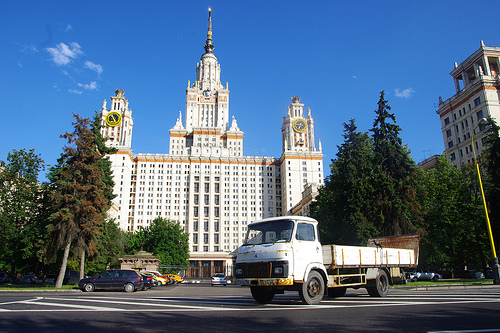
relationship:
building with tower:
[52, 22, 384, 295] [280, 95, 323, 157]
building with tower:
[52, 22, 384, 295] [169, 6, 246, 155]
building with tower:
[52, 22, 384, 295] [97, 87, 133, 154]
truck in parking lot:
[229, 215, 421, 305] [0, 280, 495, 329]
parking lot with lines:
[80, 246, 250, 330] [5, 287, 495, 308]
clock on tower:
[292, 116, 307, 133] [281, 95, 323, 154]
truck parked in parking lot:
[231, 215, 420, 305] [85, 283, 248, 291]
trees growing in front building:
[368, 113, 434, 210] [93, 2, 325, 281]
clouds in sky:
[39, 30, 97, 70] [121, 26, 180, 71]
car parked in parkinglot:
[148, 267, 184, 287] [16, 267, 495, 324]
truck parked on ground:
[229, 215, 421, 305] [0, 282, 500, 333]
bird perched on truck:
[369, 229, 384, 254] [229, 215, 421, 305]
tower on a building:
[70, 75, 158, 180] [8, 11, 394, 310]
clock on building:
[292, 118, 307, 132] [93, 2, 325, 281]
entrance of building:
[185, 255, 228, 277] [93, 2, 325, 281]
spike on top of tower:
[200, 4, 220, 55] [180, 0, 237, 131]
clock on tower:
[292, 118, 307, 132] [267, 86, 329, 193]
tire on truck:
[305, 271, 330, 303] [236, 210, 431, 302]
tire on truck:
[363, 264, 393, 299] [229, 215, 421, 305]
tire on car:
[123, 279, 138, 299] [73, 266, 145, 295]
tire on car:
[84, 283, 94, 292] [73, 266, 145, 295]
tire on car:
[81, 282, 95, 291] [72, 267, 143, 291]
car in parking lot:
[207, 267, 234, 285] [0, 280, 495, 329]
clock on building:
[292, 118, 307, 132] [43, 30, 358, 280]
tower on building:
[280, 90, 322, 170] [93, 2, 325, 281]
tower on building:
[169, 6, 246, 154] [93, 2, 325, 281]